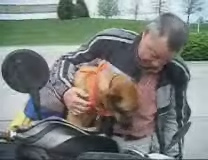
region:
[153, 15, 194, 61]
Man has short hair.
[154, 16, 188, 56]
Man has gray hair.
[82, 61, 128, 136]
Man is holding dog.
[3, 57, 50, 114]
Black mirror on bike.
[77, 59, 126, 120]
Dog is brown in color.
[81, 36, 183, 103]
Man wearing gray and black coat.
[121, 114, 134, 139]
Dog has black nose.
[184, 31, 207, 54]
Green bush across street.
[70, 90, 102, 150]
Dog is sitting on man.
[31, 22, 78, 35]
Green grass across street.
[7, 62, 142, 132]
The color of the dog is brown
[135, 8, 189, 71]
The head of the man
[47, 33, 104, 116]
The arm of the man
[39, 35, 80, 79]
The man has his elbow bent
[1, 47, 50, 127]
The rear view mirror is black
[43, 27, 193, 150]
The man has a grey and black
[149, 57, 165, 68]
The nose of the man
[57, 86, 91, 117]
The hand of the man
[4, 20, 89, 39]
The grass is short and green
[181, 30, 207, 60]
The shrub is healthy and green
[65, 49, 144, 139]
dog with orange bandana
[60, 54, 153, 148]
brown dg sitting on man's lap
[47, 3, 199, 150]
man sitting on motorcycle with dog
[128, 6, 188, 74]
white man with salt and pepper hair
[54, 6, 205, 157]
man wearing black and gray motorcycle jacket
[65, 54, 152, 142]
brown mutt wearing orange bandanna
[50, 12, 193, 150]
man wearing motorcycle jacket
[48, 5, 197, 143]
middle-aged man on motorcycle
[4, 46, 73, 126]
black rearview mirror on bike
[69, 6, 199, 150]
man wearing red t-shirt and black jacket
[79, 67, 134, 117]
dog wearing a red bandana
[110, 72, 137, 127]
big brown dog on man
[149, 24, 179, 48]
man has salt and pepper hair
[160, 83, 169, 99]
man is wearing jacket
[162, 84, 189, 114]
jacket is black and gray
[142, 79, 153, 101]
man wearing red plaid shirt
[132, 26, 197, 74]
man is sitting looking down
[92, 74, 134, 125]
dog is sitting looking down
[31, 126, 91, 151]
man has a gray and black blanket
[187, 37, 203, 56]
green and leafy bush in back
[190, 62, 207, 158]
Grey shade of the roadway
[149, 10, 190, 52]
Thatch of greying hair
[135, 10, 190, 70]
Head of an aging man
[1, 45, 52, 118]
Round shaped black mirror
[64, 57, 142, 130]
Hand holding a brown object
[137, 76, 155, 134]
Pink color of a shirt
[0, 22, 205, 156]
Man standing by a motorcycle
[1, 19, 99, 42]
Short grass lawn background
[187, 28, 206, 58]
Small bush of greenery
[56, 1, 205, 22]
Sparse growth of trees